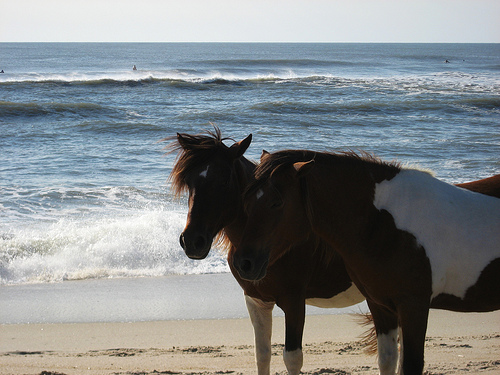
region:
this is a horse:
[225, 140, 495, 370]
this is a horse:
[165, 121, 495, 368]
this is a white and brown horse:
[228, 148, 495, 372]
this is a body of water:
[0, 208, 160, 278]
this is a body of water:
[313, 43, 495, 152]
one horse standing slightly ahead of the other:
[160, 120, 492, 365]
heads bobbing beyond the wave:
[1, 54, 454, 96]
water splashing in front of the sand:
[6, 204, 228, 309]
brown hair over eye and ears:
[157, 121, 234, 198]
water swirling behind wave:
[8, 166, 148, 238]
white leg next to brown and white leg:
[243, 292, 307, 372]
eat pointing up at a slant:
[205, 126, 258, 166]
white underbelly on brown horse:
[170, 132, 363, 309]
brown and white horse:
[255, 146, 493, 373]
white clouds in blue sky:
[402, 0, 466, 52]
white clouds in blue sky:
[300, 2, 330, 24]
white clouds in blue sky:
[257, 12, 301, 32]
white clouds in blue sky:
[212, 1, 253, 45]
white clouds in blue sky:
[76, 8, 121, 35]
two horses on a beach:
[153, 122, 488, 369]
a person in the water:
[128, 60, 141, 77]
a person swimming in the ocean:
[128, 61, 143, 74]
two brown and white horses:
[170, 123, 490, 371]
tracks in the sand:
[45, 331, 246, 373]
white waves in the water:
[2, 174, 157, 291]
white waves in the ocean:
[3, 163, 157, 291]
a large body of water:
[33, 39, 470, 118]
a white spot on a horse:
[367, 153, 496, 293]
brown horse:
[152, 135, 249, 265]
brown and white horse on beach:
[255, 129, 486, 374]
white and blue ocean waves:
[45, 132, 89, 172]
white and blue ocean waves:
[128, 183, 159, 217]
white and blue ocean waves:
[50, 205, 69, 225]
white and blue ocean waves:
[64, 66, 93, 104]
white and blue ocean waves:
[411, 65, 440, 104]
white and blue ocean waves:
[409, 132, 448, 163]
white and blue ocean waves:
[338, 54, 357, 76]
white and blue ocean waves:
[263, 65, 303, 104]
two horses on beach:
[165, 134, 495, 349]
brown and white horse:
[331, 145, 497, 362]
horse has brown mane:
[136, 134, 218, 221]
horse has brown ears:
[169, 136, 213, 208]